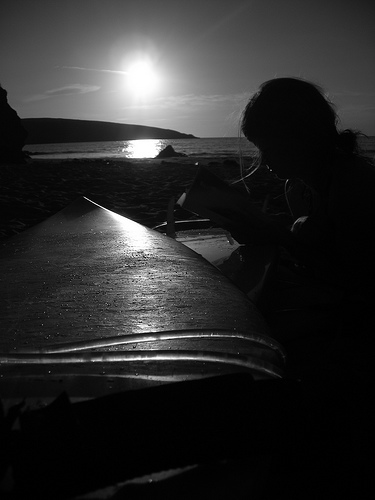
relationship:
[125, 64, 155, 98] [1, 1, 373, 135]
sun in sky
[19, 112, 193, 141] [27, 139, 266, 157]
mountain behind water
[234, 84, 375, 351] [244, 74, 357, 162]
woman has hair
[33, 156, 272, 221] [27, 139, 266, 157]
sand in front of water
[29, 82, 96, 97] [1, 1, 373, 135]
clouds in sky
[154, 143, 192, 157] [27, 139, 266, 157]
sand in front of water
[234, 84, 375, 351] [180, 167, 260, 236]
woman holding book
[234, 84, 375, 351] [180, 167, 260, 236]
woman reading book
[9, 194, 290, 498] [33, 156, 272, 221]
surfboard on sand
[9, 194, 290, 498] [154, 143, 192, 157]
surfboard on top of sand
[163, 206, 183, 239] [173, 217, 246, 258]
fin on surfboard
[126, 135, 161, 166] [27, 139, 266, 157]
reflection on water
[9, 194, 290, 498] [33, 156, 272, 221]
surfboard on top of sand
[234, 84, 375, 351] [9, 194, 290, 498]
woman sitting next to surfboard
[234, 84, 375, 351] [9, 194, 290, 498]
woman next to surfboard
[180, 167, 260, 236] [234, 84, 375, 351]
book being red by woman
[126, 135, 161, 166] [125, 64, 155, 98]
reflection of sun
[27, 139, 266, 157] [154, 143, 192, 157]
water behind sand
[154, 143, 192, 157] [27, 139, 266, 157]
sand near water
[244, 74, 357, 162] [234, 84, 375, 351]
hair on woman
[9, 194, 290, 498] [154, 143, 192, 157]
surfboard on sand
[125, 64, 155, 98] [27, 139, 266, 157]
sun rising over water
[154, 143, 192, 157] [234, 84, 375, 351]
sand behind woman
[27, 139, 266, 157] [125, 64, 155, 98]
water under sun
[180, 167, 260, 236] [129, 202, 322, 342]
book on beach